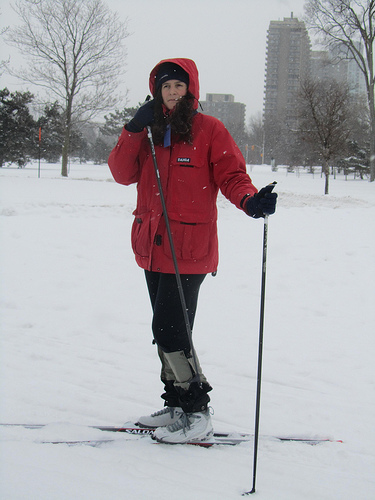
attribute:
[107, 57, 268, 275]
jacket — red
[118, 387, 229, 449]
shoes — white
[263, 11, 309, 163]
building — tall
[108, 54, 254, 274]
ski jacket — red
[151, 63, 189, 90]
cap — black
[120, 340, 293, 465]
boots — ski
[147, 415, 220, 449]
ski boot — white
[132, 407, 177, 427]
ski boot — white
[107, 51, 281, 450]
woman — standing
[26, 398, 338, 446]
skiis — red, black, white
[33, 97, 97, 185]
tree — snow covered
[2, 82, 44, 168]
tree — snow covered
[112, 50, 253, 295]
coat — red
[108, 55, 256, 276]
coat — red, red hooded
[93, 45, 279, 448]
skier — female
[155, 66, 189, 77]
cap — black